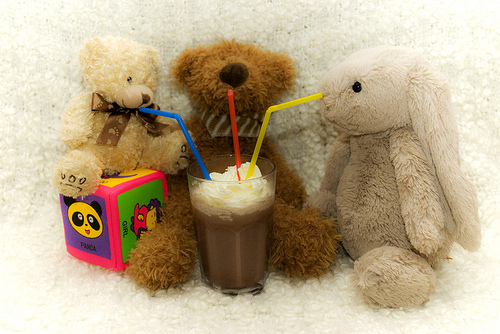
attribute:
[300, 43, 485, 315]
rabbit — stuffed, plush toy, light brown, snuggly, cuddly, in need of sponging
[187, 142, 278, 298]
chocolate soda — brown, chocolate shake, like root beer float, yummy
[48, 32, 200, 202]
bear — stuffed, plush toy, teddy, awfully small, golden brown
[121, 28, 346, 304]
bear — teddy, stuffed, plush toy, honey brown, frizzy fluffed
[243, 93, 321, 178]
straw — yellow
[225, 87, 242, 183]
straw — red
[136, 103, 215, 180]
straw — blue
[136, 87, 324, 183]
straws — perky primary colors, all plastic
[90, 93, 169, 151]
ribbon — milk chocolate brown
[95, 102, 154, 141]
paw prints — tan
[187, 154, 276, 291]
glass — not really full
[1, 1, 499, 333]
blanket — white, woolly, fluffy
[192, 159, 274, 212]
whipped cream — floating, white, yummy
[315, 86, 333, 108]
nose — beigey pink, plush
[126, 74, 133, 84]
eye — dark, proably glass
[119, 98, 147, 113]
mouth — smiling, embroidery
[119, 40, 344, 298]
big bear — frizzy but soft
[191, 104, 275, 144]
neckerchief — soft, striped, brown, cream, brown+cream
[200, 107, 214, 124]
stripe — brown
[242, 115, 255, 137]
stripe — brown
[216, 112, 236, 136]
stripe — brown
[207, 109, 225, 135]
stripe — brown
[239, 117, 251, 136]
stripe — cream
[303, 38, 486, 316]
bunster — hiding second eye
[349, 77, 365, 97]
eye — dark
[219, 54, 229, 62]
eye — almost hidden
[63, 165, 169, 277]
block — also soft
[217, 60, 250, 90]
nose — maybe velvet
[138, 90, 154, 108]
nose — embroidered, brown, soft, plush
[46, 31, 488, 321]
plush toys — three, imaginary friends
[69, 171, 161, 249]
drawings — in color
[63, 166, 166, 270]
outline — hot pink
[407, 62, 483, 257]
ear — long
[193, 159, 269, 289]
soda+cream together — extra yummy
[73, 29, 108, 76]
ear — small, rounded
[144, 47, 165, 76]
ear — small, rounded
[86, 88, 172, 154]
bow — professionally tied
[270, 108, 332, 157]
dirt — likely chocolate, behind bunster, beside big bear